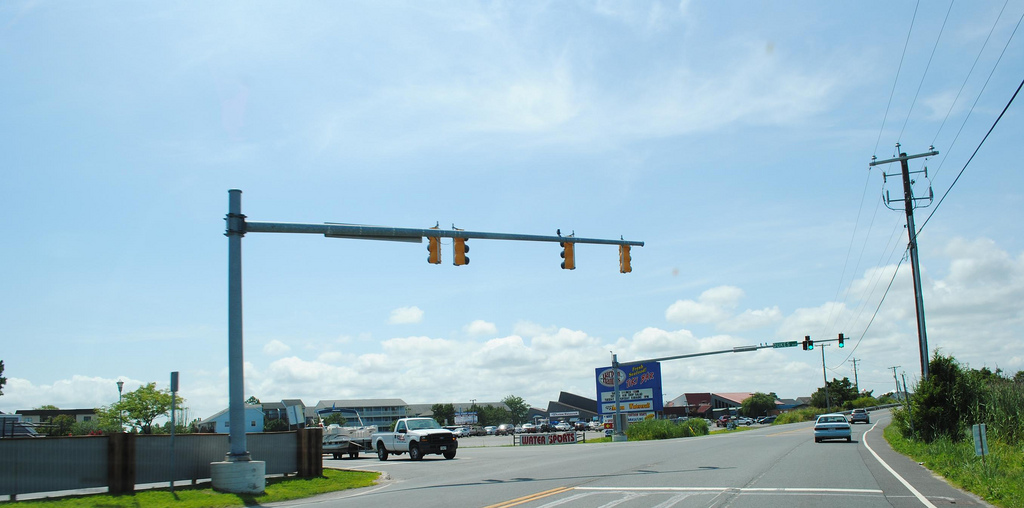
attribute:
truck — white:
[360, 410, 466, 469]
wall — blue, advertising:
[594, 351, 677, 425]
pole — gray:
[216, 234, 273, 496]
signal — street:
[432, 227, 638, 267]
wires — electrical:
[248, 1, 992, 364]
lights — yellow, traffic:
[413, 224, 651, 272]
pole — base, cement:
[205, 449, 281, 501]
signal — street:
[446, 229, 477, 268]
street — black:
[283, 392, 1005, 503]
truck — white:
[373, 413, 451, 459]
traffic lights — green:
[791, 317, 854, 357]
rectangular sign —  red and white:
[478, 419, 593, 458]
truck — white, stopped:
[370, 413, 461, 461]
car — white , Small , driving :
[815, 413, 854, 440]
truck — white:
[387, 441, 450, 470]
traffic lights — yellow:
[394, 210, 682, 301]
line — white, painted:
[538, 465, 889, 502]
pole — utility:
[828, 161, 989, 460]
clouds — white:
[359, 363, 440, 381]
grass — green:
[258, 471, 311, 497]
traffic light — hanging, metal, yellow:
[409, 214, 444, 271]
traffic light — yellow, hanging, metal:
[450, 225, 468, 265]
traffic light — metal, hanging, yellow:
[539, 223, 589, 280]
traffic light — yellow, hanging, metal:
[525, 223, 601, 303]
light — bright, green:
[759, 320, 824, 366]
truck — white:
[350, 413, 497, 470]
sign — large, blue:
[562, 344, 697, 440]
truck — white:
[332, 402, 533, 480]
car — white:
[790, 396, 950, 502]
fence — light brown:
[47, 413, 287, 496]